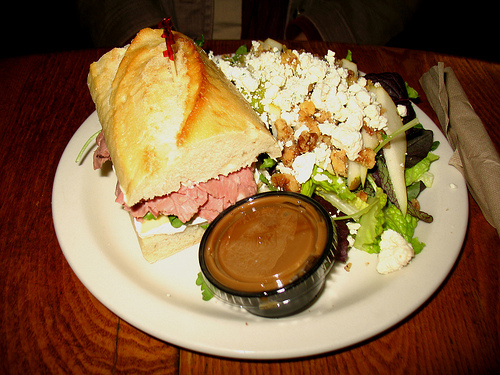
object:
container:
[198, 195, 355, 324]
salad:
[234, 42, 489, 246]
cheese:
[281, 72, 402, 195]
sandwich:
[85, 24, 281, 260]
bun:
[86, 27, 278, 206]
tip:
[160, 17, 179, 59]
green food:
[305, 165, 434, 255]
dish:
[41, 43, 465, 357]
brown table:
[0, 40, 498, 373]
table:
[1, 42, 498, 374]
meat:
[86, 130, 260, 228]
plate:
[50, 99, 470, 359]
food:
[72, 26, 441, 318]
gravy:
[193, 185, 343, 324]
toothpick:
[154, 10, 194, 81]